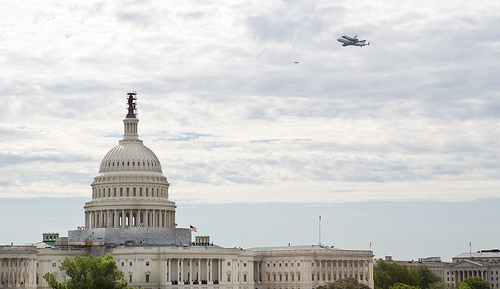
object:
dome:
[83, 87, 177, 229]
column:
[166, 258, 172, 284]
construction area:
[54, 225, 192, 248]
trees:
[320, 259, 488, 288]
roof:
[101, 118, 160, 166]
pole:
[318, 215, 322, 247]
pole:
[469, 242, 472, 255]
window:
[145, 272, 150, 283]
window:
[242, 274, 248, 282]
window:
[446, 271, 450, 276]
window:
[291, 272, 300, 281]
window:
[137, 161, 140, 166]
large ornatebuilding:
[0, 91, 375, 288]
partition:
[67, 225, 191, 247]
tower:
[122, 92, 139, 137]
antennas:
[125, 87, 137, 118]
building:
[373, 238, 499, 288]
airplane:
[336, 34, 370, 48]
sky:
[0, 0, 499, 261]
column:
[135, 209, 143, 227]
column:
[119, 185, 147, 197]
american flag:
[190, 224, 198, 233]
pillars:
[312, 260, 370, 283]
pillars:
[83, 204, 177, 228]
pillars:
[165, 256, 220, 285]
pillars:
[259, 260, 303, 284]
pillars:
[123, 120, 139, 135]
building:
[0, 91, 376, 289]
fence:
[67, 227, 191, 247]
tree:
[41, 252, 127, 289]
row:
[81, 196, 176, 229]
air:
[0, 0, 499, 207]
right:
[385, 0, 498, 286]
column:
[196, 258, 206, 286]